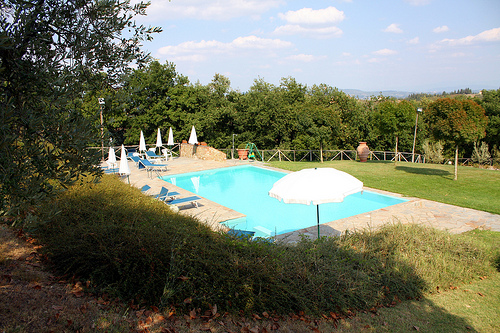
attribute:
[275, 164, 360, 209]
umbrella — white, open, here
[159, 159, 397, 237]
pool — here, rectangular shaped, rectangular, blue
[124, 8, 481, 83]
clouds — white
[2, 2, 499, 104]
sky — blue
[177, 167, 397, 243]
water — blue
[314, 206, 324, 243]
pole — black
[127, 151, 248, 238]
chairs — blue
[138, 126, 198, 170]
umbrellas — closed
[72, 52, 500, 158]
trees — lined up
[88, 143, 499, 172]
fencing — wood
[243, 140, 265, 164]
swing set — green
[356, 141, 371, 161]
vase — large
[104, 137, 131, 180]
umbrellas — closed